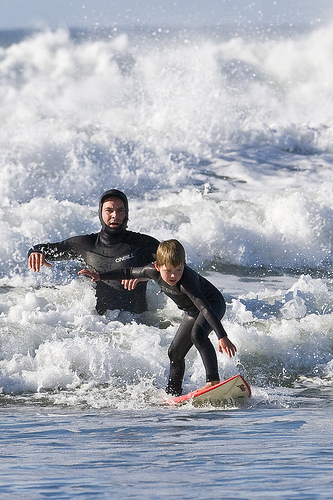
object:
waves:
[0, 25, 333, 413]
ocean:
[0, 21, 333, 500]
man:
[28, 189, 162, 316]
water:
[1, 30, 333, 499]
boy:
[78, 239, 237, 398]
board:
[163, 374, 251, 403]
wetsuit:
[98, 264, 227, 397]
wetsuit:
[28, 189, 162, 317]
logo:
[237, 384, 247, 392]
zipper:
[156, 289, 162, 295]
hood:
[98, 189, 129, 235]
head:
[98, 189, 128, 234]